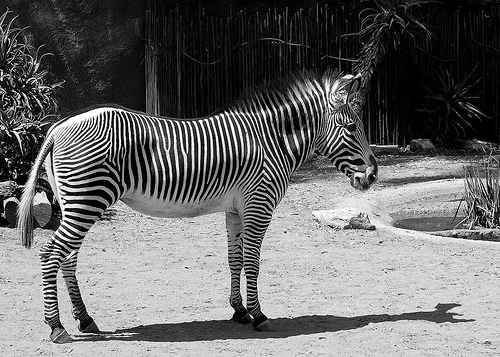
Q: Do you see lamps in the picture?
A: No, there are no lamps.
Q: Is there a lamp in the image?
A: No, there are no lamps.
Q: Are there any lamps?
A: No, there are no lamps.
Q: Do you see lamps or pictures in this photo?
A: No, there are no lamps or pictures.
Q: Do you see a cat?
A: No, there are no cats.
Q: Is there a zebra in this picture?
A: Yes, there is a zebra.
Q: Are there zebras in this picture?
A: Yes, there is a zebra.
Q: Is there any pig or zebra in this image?
A: Yes, there is a zebra.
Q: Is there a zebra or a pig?
A: Yes, there is a zebra.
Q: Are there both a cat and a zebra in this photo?
A: No, there is a zebra but no cats.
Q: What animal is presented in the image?
A: The animal is a zebra.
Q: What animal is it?
A: The animal is a zebra.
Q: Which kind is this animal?
A: That is a zebra.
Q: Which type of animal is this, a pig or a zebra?
A: That is a zebra.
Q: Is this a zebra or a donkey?
A: This is a zebra.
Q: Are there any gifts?
A: No, there are no gifts.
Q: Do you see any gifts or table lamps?
A: No, there are no gifts or table lamps.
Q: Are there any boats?
A: No, there are no boats.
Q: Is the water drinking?
A: Yes, the water is drinking.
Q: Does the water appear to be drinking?
A: Yes, the water is drinking.